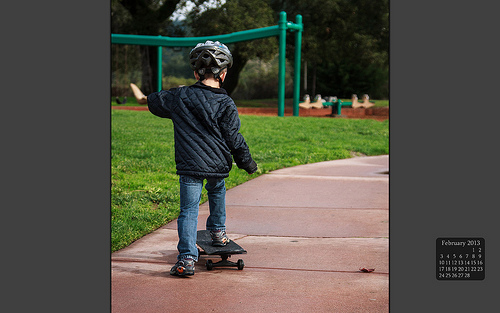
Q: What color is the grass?
A: Green.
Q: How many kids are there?
A: One.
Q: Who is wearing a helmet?
A: A boy.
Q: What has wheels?
A: Skateboard.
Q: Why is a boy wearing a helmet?
A: Boy is skateboarding.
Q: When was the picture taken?
A: Daytime.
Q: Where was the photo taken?
A: At a park.